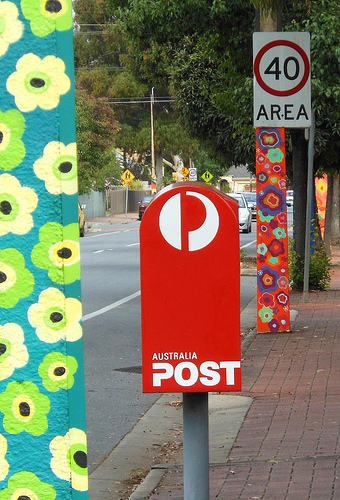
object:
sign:
[252, 30, 312, 129]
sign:
[141, 184, 242, 393]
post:
[0, 0, 90, 499]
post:
[254, 127, 291, 333]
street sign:
[121, 169, 135, 183]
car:
[225, 192, 254, 233]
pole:
[150, 89, 157, 181]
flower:
[30, 221, 80, 286]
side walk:
[128, 245, 339, 500]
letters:
[256, 104, 309, 121]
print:
[0, 50, 76, 126]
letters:
[152, 351, 241, 388]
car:
[138, 195, 155, 220]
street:
[79, 222, 258, 498]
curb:
[126, 467, 169, 500]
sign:
[189, 167, 197, 181]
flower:
[257, 265, 280, 293]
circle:
[253, 39, 310, 97]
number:
[264, 55, 300, 80]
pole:
[303, 106, 319, 293]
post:
[125, 185, 128, 216]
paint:
[83, 290, 141, 324]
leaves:
[129, 0, 164, 28]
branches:
[164, 23, 252, 88]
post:
[182, 391, 209, 499]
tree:
[118, 0, 340, 265]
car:
[78, 201, 87, 237]